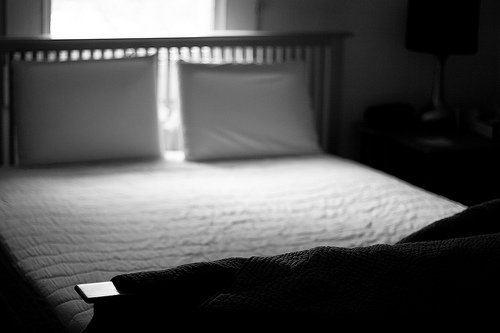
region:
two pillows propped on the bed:
[9, 58, 323, 157]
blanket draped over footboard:
[121, 225, 499, 325]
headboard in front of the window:
[5, 30, 338, 145]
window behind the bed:
[44, 8, 231, 121]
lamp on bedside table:
[401, 4, 485, 139]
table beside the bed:
[356, 118, 498, 199]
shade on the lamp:
[405, 1, 472, 53]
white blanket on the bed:
[2, 146, 469, 319]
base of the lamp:
[422, 110, 451, 126]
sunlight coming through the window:
[50, 13, 226, 103]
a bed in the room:
[3, 29, 490, 325]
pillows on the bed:
[7, 58, 324, 167]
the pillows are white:
[9, 57, 329, 157]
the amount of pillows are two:
[6, 57, 330, 172]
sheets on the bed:
[2, 165, 448, 327]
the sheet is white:
[3, 165, 456, 330]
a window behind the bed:
[27, 2, 285, 125]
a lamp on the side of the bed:
[395, 0, 486, 118]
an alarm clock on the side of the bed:
[358, 98, 420, 139]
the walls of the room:
[5, 9, 499, 149]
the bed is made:
[6, 36, 497, 314]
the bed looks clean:
[8, 40, 486, 330]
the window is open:
[39, 0, 261, 166]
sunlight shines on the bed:
[42, 120, 417, 254]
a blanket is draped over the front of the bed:
[95, 227, 494, 325]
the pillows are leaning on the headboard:
[4, 31, 348, 168]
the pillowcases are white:
[3, 52, 340, 187]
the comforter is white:
[8, 126, 483, 320]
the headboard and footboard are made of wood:
[2, 33, 486, 330]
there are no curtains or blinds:
[46, 1, 240, 131]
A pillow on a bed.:
[14, 58, 162, 165]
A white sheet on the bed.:
[6, 148, 455, 270]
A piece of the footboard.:
[76, 278, 124, 308]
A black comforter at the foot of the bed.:
[108, 235, 498, 330]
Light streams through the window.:
[32, 2, 259, 35]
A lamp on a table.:
[393, 1, 483, 127]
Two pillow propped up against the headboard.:
[1, 34, 342, 158]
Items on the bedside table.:
[468, 100, 497, 142]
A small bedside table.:
[358, 75, 498, 195]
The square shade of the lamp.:
[399, 0, 489, 66]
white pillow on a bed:
[162, 46, 328, 165]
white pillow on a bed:
[7, 42, 172, 179]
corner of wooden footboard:
[70, 275, 125, 307]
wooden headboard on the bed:
[0, 20, 360, 162]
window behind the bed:
[48, 3, 222, 46]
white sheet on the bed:
[0, 130, 470, 330]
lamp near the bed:
[388, 1, 489, 131]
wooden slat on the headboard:
[162, 43, 178, 109]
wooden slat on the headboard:
[314, 44, 333, 153]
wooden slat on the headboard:
[270, 42, 280, 65]